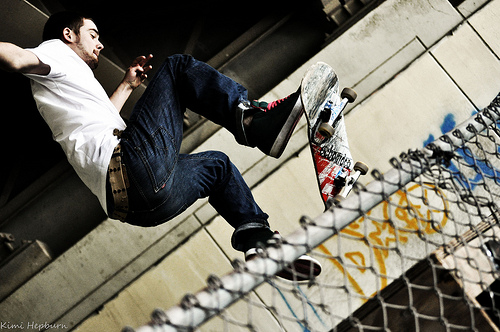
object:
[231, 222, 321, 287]
left sneaker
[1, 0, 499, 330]
concrete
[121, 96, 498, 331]
fence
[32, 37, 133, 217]
shirt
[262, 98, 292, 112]
shoelaces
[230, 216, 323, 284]
shoes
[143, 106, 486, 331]
pole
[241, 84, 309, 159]
shoe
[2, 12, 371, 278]
man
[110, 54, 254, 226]
blue jeans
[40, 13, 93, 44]
hair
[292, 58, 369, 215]
skateboard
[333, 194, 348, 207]
wheel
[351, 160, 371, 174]
wheel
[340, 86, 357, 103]
wheel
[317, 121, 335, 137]
wheel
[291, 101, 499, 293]
graffiti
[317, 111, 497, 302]
letters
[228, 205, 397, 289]
shoe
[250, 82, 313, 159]
foot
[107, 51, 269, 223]
pants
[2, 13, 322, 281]
boy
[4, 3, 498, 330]
wall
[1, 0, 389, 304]
tricks